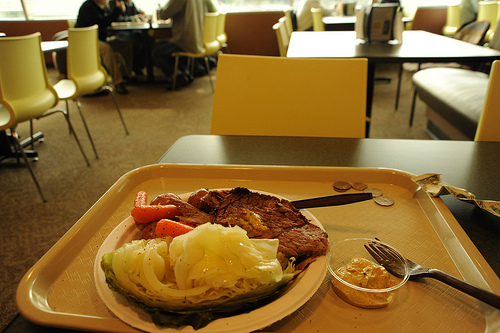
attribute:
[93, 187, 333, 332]
plate — paper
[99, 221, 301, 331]
cabbage — cooked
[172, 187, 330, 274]
corned beef — brown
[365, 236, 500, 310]
fork — plastic, black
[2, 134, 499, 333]
table — wooden, brown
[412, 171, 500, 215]
dollar — wrinkled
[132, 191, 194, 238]
carrots — cooked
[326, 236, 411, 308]
plastic cup — small, clear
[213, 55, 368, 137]
chair — empty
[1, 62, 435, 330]
rug — brown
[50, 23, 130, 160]
chair — yellow, silver, metal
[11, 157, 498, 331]
tray — yellow